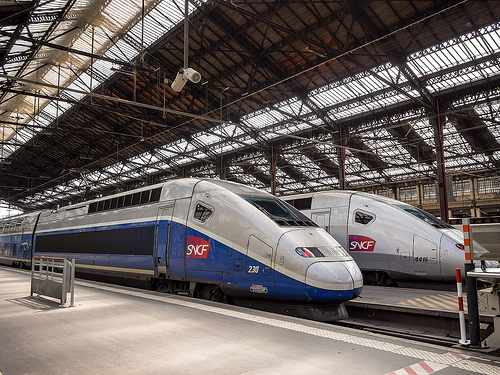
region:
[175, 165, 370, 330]
Front of passenger train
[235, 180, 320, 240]
Windshield for passenger train locomotive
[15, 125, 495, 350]
Two trains inside train station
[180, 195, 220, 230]
Side window for train locomotive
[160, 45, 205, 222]
Lights inside train station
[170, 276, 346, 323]
Wheels for train locomotive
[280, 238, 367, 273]
Lights on front of train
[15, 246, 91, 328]
Equipment on train station platform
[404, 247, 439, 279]
Numbers on train locomotive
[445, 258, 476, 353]
Marker on train tracks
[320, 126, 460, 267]
A train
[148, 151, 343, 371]
A train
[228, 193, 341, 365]
A train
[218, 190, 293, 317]
A train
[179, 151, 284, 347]
A train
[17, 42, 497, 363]
A train station scene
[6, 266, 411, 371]
This area is called a platform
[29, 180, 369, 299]
This is a high-speed train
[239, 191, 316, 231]
The train's wind screen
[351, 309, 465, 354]
The train tracks are here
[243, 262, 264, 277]
The train's identification number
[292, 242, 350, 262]
These are the train's headlights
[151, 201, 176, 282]
The train's door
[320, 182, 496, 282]
Another train is shown in the background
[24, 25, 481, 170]
The station has a high roof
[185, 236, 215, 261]
A sign that says "SNCF"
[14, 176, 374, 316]
a train in a train station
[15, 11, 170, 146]
the roof of a train station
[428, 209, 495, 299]
warning rails in a train station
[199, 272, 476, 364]
train tracks in a train station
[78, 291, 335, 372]
A ramp in a train depot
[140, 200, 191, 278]
the door to a train parked in a train station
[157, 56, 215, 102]
loudspeakers in a train station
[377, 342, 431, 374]
red and white warning stripes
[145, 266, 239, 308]
the wheels on a train in a train station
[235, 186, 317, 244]
windshield of speed train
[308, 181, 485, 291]
gray speed tain on track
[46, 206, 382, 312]
gray speed train with blue stripe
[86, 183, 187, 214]
upper passenger windows of train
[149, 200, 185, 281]
door for speed train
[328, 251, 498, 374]
metal train track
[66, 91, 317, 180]
metal beams above train terminal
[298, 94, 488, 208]
metal structure of train terminal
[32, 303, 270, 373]
cement of train terminal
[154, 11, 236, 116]
lights hanging from ceiling